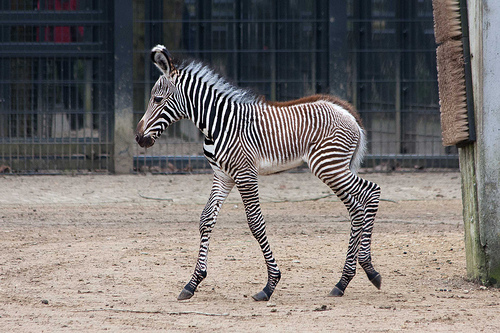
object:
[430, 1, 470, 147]
brush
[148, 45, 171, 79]
ears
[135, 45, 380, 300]
zebra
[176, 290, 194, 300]
hoof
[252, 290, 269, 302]
hoof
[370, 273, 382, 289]
hoof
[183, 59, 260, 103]
mane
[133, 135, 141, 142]
nose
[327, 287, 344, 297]
black hoof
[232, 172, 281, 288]
leg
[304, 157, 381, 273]
leg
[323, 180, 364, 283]
leg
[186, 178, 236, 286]
leg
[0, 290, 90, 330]
dirt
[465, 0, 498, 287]
wall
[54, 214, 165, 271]
ground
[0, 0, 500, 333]
enclosure